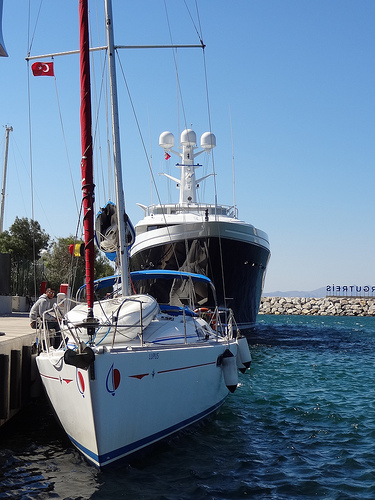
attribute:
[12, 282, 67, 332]
man — wearing, sitting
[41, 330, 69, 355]
pants — long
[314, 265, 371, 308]
sign — here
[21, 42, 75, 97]
flag — up, waving, national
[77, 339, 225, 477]
boat — painted, small, white, designed, here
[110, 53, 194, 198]
line — across, red, running, blue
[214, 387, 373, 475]
water — blue, here, turqoise, green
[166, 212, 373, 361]
yacht — black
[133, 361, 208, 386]
stripe — red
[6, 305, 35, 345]
surface — concrete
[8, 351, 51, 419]
letters — black, supported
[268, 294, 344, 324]
wall — rock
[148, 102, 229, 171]
antennas — white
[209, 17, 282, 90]
skies — blue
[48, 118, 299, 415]
boats — here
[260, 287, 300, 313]
shore — rocky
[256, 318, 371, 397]
sea — unforgiving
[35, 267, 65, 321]
person — enjoying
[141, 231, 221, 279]
boat — black, larger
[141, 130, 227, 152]
radar — here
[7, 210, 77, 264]
trees — here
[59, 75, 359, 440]
harbor — here